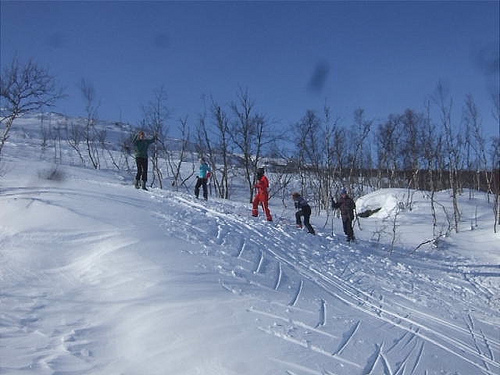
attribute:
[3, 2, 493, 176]
sky — blue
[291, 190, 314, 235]
person — taking a step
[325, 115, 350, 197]
tree — bare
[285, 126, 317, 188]
tree — bare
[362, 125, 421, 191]
tree — bare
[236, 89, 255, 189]
tree — bare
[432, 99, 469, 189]
tree — bare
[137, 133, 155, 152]
jacket — green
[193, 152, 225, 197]
coat — blue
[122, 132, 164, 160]
snow jacket — grey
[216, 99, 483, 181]
trees — don't have leaves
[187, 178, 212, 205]
pants — black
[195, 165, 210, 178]
coat — light blue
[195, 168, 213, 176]
jacket — blue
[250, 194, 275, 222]
red pants — pair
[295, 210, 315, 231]
pants — black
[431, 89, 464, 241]
tree — with no leaves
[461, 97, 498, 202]
tree — with no leaves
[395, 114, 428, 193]
tree — with no leaves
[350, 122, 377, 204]
tree — with no leaves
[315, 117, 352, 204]
tree — with no leaves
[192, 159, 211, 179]
jacket — light, blue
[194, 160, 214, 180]
jacket — blue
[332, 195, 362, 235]
snowsuit — black